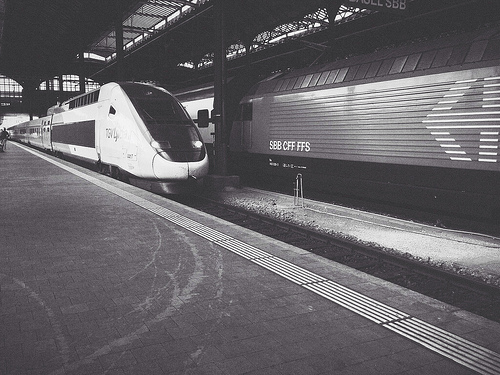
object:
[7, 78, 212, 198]
train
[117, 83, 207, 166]
hood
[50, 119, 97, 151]
window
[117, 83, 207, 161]
window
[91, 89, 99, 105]
window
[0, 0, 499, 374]
terminal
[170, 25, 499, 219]
train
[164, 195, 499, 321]
track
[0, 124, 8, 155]
people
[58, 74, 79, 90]
windows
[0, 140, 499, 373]
floor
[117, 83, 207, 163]
windshield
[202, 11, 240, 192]
support beam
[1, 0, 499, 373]
train station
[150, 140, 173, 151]
headlights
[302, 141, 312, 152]
lettering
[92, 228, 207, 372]
stains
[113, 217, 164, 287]
stains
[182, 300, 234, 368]
stains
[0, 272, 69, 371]
stains